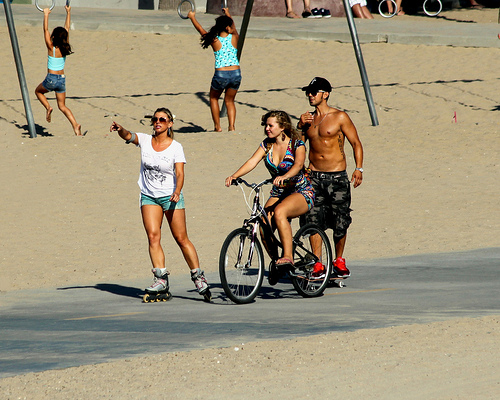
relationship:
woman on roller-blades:
[105, 103, 216, 302] [137, 289, 217, 306]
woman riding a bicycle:
[222, 103, 326, 274] [215, 171, 338, 308]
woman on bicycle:
[222, 103, 326, 274] [215, 171, 338, 308]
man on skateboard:
[293, 72, 369, 290] [310, 273, 353, 290]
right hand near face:
[296, 103, 321, 133] [305, 88, 328, 108]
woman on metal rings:
[27, 3, 92, 143] [34, 0, 73, 10]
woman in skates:
[105, 103, 216, 302] [136, 287, 137, 288]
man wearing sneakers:
[293, 72, 369, 290] [312, 257, 353, 279]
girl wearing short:
[27, 3, 92, 143] [40, 71, 68, 95]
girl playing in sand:
[27, 3, 92, 143] [12, 61, 113, 161]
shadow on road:
[56, 273, 142, 298] [8, 247, 496, 365]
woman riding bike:
[222, 103, 326, 274] [215, 171, 338, 308]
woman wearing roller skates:
[105, 103, 216, 302] [137, 289, 217, 306]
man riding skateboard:
[293, 72, 369, 290] [310, 273, 353, 290]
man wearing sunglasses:
[293, 72, 369, 290] [305, 85, 324, 95]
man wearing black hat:
[293, 72, 369, 290] [297, 74, 337, 92]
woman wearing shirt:
[105, 103, 216, 302] [131, 128, 186, 199]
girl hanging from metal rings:
[27, 3, 92, 143] [30, 0, 58, 15]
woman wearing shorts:
[105, 103, 216, 302] [137, 191, 185, 211]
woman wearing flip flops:
[222, 103, 326, 274] [266, 256, 301, 271]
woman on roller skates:
[105, 103, 216, 302] [137, 289, 217, 306]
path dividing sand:
[8, 247, 496, 365] [15, 160, 497, 399]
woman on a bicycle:
[222, 103, 326, 274] [215, 171, 338, 308]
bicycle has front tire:
[215, 171, 338, 308] [213, 221, 269, 308]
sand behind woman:
[12, 61, 113, 161] [105, 103, 216, 302]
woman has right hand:
[222, 103, 326, 274] [223, 146, 269, 191]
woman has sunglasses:
[105, 103, 216, 302] [149, 113, 170, 126]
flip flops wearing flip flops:
[266, 256, 301, 271] [266, 256, 301, 266]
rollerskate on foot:
[138, 261, 175, 306] [138, 279, 178, 309]